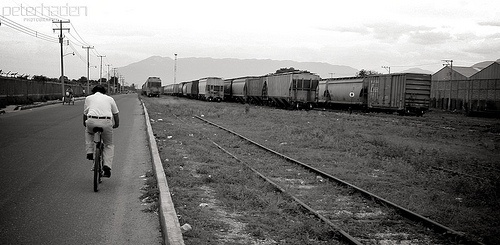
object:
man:
[80, 83, 122, 177]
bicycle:
[90, 124, 108, 193]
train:
[310, 73, 403, 117]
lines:
[32, 27, 49, 41]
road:
[24, 141, 32, 148]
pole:
[60, 39, 66, 99]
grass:
[164, 161, 197, 218]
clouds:
[352, 2, 369, 6]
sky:
[214, 5, 231, 13]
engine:
[269, 85, 304, 107]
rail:
[237, 116, 284, 173]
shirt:
[82, 91, 120, 117]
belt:
[96, 115, 100, 120]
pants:
[82, 117, 116, 169]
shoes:
[98, 164, 115, 178]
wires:
[27, 13, 67, 32]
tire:
[89, 174, 105, 191]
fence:
[3, 84, 47, 112]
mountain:
[140, 48, 184, 68]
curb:
[141, 93, 165, 153]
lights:
[82, 42, 115, 66]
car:
[186, 76, 225, 99]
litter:
[339, 98, 466, 185]